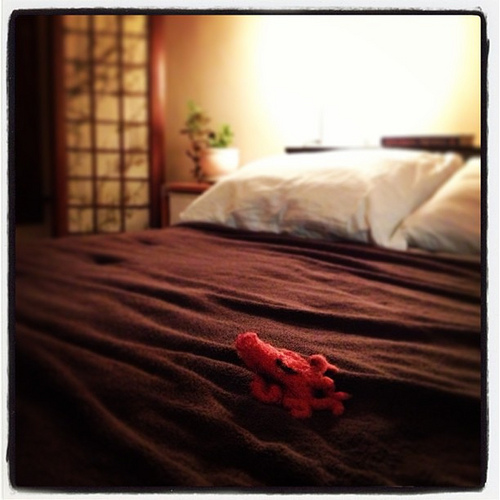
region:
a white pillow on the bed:
[207, 139, 417, 246]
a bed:
[21, 157, 492, 498]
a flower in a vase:
[185, 100, 231, 182]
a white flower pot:
[191, 143, 241, 178]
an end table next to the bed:
[156, 164, 213, 232]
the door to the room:
[57, 15, 176, 224]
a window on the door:
[94, 123, 121, 148]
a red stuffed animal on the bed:
[225, 322, 339, 421]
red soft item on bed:
[231, 330, 348, 438]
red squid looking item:
[188, 321, 378, 421]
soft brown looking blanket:
[48, 254, 178, 431]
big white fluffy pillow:
[162, 135, 404, 249]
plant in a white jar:
[168, 106, 252, 194]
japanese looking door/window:
[68, 24, 146, 210]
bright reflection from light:
[216, 40, 408, 140]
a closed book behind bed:
[360, 110, 480, 168]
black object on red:
[260, 340, 290, 381]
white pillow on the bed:
[174, 125, 459, 255]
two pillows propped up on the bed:
[173, 140, 481, 259]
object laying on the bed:
[233, 321, 368, 435]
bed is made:
[7, 133, 484, 498]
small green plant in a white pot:
[180, 102, 250, 186]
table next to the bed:
[154, 176, 226, 226]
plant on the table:
[181, 107, 251, 185]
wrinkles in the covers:
[58, 297, 477, 487]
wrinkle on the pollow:
[356, 196, 385, 242]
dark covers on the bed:
[14, 224, 482, 486]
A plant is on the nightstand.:
[180, 100, 240, 173]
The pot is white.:
[199, 149, 239, 168]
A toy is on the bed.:
[229, 331, 347, 418]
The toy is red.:
[245, 343, 268, 363]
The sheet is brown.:
[22, 266, 206, 458]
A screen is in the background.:
[63, 13, 153, 208]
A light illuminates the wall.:
[230, 15, 472, 117]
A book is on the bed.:
[379, 135, 476, 148]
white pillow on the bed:
[163, 135, 462, 263]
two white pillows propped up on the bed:
[174, 138, 486, 260]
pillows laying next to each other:
[173, 140, 485, 265]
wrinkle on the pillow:
[351, 195, 384, 242]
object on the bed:
[228, 325, 354, 427]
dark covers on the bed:
[13, 222, 487, 487]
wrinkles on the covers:
[13, 254, 488, 488]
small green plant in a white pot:
[178, 106, 243, 180]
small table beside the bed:
[156, 171, 234, 239]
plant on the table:
[178, 103, 238, 185]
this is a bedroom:
[47, 33, 441, 447]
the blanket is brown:
[47, 231, 264, 398]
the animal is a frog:
[202, 299, 413, 454]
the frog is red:
[223, 310, 369, 432]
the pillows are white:
[208, 152, 412, 259]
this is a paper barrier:
[32, 60, 172, 242]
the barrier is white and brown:
[11, 71, 161, 177]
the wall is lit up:
[193, 45, 320, 150]